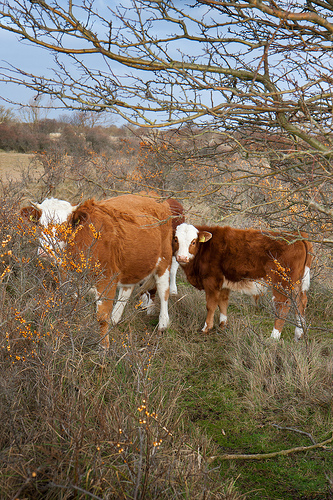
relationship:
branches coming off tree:
[208, 423, 332, 461] [0, 0, 331, 247]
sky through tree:
[1, 0, 332, 135] [0, 0, 331, 247]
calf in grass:
[172, 222, 313, 341] [47, 330, 324, 347]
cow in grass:
[19, 190, 173, 361] [47, 330, 324, 347]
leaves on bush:
[2, 221, 101, 288] [7, 216, 123, 498]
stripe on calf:
[170, 219, 200, 260] [172, 222, 313, 341]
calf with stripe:
[172, 222, 313, 341] [170, 219, 200, 260]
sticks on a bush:
[11, 330, 191, 485] [6, 114, 189, 188]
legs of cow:
[51, 255, 183, 355] [19, 190, 173, 361]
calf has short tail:
[172, 222, 313, 341] [299, 237, 311, 294]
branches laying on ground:
[208, 434, 332, 461] [133, 349, 316, 497]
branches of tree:
[1, 1, 332, 247] [0, 0, 331, 247]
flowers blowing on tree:
[23, 216, 105, 292] [9, 99, 185, 329]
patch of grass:
[179, 372, 278, 457] [174, 345, 330, 493]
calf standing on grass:
[172, 222, 313, 341] [192, 321, 279, 378]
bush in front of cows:
[0, 216, 246, 500] [19, 188, 314, 351]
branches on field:
[208, 434, 332, 461] [0, 128, 332, 500]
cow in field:
[13, 192, 178, 357] [2, 159, 332, 497]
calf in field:
[172, 222, 313, 341] [2, 159, 332, 497]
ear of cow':
[198, 228, 213, 244] [8, 152, 240, 340]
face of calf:
[173, 219, 207, 267] [172, 222, 313, 341]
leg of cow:
[112, 280, 140, 332] [28, 185, 171, 355]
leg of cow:
[155, 256, 172, 331] [28, 185, 171, 355]